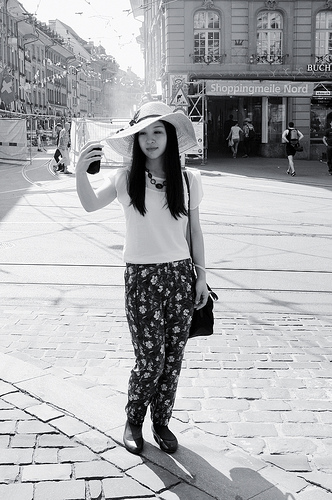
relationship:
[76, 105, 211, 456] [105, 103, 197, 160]
woman wearing hat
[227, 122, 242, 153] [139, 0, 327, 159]
person entering store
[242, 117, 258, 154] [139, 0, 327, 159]
person entering store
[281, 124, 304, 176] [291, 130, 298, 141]
person carrying backpack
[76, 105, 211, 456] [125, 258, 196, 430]
woman wearing pants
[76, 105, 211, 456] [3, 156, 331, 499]
woman standing on plaza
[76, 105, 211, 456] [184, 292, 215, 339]
woman holding purse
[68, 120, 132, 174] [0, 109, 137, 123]
sheet hanging on line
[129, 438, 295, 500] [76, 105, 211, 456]
shadow of woman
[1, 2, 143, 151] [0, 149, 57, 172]
buildings along street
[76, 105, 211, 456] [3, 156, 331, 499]
woman on side of plaza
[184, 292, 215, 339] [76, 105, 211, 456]
purse on woman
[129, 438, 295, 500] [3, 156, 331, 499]
shadow on plaza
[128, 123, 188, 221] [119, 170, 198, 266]
hair on blouse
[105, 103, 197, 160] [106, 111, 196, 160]
hat with brim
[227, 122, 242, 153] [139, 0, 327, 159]
person walking into store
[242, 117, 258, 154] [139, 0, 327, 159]
person walking into store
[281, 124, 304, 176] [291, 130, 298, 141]
person wearing backpack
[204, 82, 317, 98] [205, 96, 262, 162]
sign above doorway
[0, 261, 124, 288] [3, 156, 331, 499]
shadows in plaza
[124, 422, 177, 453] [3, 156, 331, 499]
shoes on plaza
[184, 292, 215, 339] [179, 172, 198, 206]
purse on shoulder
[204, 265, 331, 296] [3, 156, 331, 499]
tracks on plaza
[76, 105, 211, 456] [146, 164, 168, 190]
woman with a necklace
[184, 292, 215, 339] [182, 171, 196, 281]
purse with strap